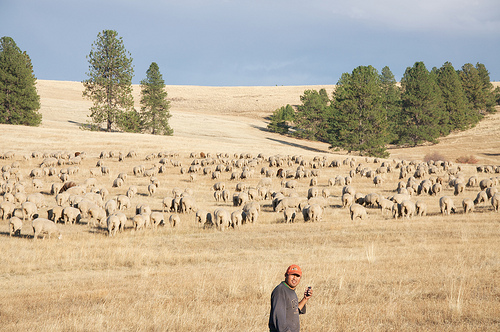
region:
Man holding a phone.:
[258, 253, 313, 328]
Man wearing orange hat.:
[260, 255, 320, 326]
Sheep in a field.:
[0, 142, 492, 217]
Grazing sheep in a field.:
[0, 145, 495, 200]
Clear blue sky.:
[201, 2, 496, 32]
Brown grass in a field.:
[325, 241, 475, 286]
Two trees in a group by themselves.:
[75, 20, 180, 135]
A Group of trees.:
[260, 60, 495, 125]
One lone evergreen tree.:
[0, 30, 45, 125]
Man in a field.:
[230, 255, 322, 328]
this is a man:
[268, 260, 315, 330]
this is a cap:
[288, 265, 300, 272]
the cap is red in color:
[289, 266, 296, 271]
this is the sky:
[158, 10, 410, 52]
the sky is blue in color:
[173, 3, 265, 44]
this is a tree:
[86, 25, 131, 128]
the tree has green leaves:
[141, 70, 167, 122]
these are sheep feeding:
[40, 178, 152, 220]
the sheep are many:
[28, 165, 380, 222]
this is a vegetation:
[133, 266, 218, 309]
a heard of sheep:
[0, 148, 499, 241]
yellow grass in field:
[65, 265, 217, 306]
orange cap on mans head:
[286, 261, 304, 278]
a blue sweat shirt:
[264, 281, 307, 331]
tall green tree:
[78, 28, 144, 142]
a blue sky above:
[155, 8, 295, 50]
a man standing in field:
[269, 263, 315, 330]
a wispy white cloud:
[318, 0, 498, 32]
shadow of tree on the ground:
[263, 133, 334, 155]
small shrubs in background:
[425, 148, 480, 165]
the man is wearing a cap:
[288, 263, 300, 274]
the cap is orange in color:
[288, 262, 300, 272]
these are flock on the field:
[4, 151, 470, 231]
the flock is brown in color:
[2, 153, 476, 235]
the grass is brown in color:
[1, 243, 248, 328]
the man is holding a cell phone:
[306, 281, 313, 296]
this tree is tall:
[85, 35, 130, 131]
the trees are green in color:
[323, 71, 473, 138]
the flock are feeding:
[0, 157, 490, 241]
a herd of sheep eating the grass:
[9, 143, 498, 228]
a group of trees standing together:
[266, 60, 498, 154]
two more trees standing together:
[80, 28, 171, 133]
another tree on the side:
[4, 37, 49, 123]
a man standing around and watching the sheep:
[268, 263, 319, 330]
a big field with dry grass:
[5, 82, 497, 329]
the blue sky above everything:
[3, 3, 493, 85]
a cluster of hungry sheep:
[54, 172, 122, 232]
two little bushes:
[416, 142, 482, 170]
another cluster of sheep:
[417, 160, 450, 179]